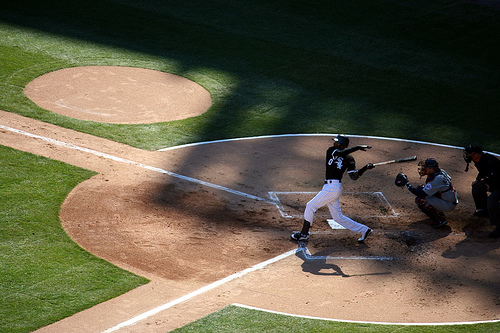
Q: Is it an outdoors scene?
A: Yes, it is outdoors.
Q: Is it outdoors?
A: Yes, it is outdoors.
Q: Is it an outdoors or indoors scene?
A: It is outdoors.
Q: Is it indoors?
A: No, it is outdoors.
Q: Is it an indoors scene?
A: No, it is outdoors.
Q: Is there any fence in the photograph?
A: No, there are no fences.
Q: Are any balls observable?
A: No, there are no balls.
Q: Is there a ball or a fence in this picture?
A: No, there are no balls or fences.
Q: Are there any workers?
A: No, there are no workers.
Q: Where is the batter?
A: The batter is in the field.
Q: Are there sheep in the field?
A: No, there is a batter in the field.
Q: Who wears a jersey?
A: The batter wears a jersey.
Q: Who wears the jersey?
A: The batter wears a jersey.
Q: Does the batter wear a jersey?
A: Yes, the batter wears a jersey.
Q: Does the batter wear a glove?
A: No, the batter wears a jersey.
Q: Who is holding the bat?
A: The batter is holding the bat.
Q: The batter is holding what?
A: The batter is holding the bat.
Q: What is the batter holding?
A: The batter is holding the bat.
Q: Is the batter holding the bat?
A: Yes, the batter is holding the bat.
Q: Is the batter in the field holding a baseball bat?
A: No, the batter is holding the bat.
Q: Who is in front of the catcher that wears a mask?
A: The batter is in front of the catcher.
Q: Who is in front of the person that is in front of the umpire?
A: The batter is in front of the catcher.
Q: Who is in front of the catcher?
A: The batter is in front of the catcher.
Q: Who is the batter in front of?
A: The batter is in front of the catcher.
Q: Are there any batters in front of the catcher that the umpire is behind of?
A: Yes, there is a batter in front of the catcher.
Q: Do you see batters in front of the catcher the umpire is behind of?
A: Yes, there is a batter in front of the catcher.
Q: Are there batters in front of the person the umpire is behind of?
A: Yes, there is a batter in front of the catcher.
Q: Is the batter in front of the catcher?
A: Yes, the batter is in front of the catcher.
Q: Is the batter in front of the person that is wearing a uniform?
A: Yes, the batter is in front of the catcher.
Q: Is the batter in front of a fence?
A: No, the batter is in front of the catcher.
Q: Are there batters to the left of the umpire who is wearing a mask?
A: Yes, there is a batter to the left of the umpire.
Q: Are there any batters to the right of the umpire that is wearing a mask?
A: No, the batter is to the left of the umpire.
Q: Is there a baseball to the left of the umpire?
A: No, there is a batter to the left of the umpire.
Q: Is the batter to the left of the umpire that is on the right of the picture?
A: Yes, the batter is to the left of the umpire.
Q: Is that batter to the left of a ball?
A: No, the batter is to the left of the umpire.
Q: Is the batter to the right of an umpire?
A: No, the batter is to the left of an umpire.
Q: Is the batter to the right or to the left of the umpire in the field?
A: The batter is to the left of the umpire.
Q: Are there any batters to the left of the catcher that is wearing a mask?
A: Yes, there is a batter to the left of the catcher.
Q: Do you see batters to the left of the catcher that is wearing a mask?
A: Yes, there is a batter to the left of the catcher.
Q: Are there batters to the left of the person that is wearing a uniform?
A: Yes, there is a batter to the left of the catcher.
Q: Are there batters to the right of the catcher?
A: No, the batter is to the left of the catcher.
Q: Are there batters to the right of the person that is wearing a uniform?
A: No, the batter is to the left of the catcher.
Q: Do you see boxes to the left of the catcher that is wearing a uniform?
A: No, there is a batter to the left of the catcher.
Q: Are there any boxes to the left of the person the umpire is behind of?
A: No, there is a batter to the left of the catcher.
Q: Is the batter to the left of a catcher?
A: Yes, the batter is to the left of a catcher.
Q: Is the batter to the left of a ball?
A: No, the batter is to the left of a catcher.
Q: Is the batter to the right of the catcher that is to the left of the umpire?
A: No, the batter is to the left of the catcher.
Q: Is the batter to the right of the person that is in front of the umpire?
A: No, the batter is to the left of the catcher.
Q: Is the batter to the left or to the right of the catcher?
A: The batter is to the left of the catcher.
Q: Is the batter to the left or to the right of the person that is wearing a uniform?
A: The batter is to the left of the catcher.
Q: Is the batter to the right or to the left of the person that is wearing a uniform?
A: The batter is to the left of the catcher.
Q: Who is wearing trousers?
A: The batter is wearing trousers.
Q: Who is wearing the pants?
A: The batter is wearing trousers.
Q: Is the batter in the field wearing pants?
A: Yes, the batter is wearing pants.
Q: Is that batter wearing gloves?
A: No, the batter is wearing pants.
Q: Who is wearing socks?
A: The batter is wearing socks.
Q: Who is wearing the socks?
A: The batter is wearing socks.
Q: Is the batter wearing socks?
A: Yes, the batter is wearing socks.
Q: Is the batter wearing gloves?
A: No, the batter is wearing socks.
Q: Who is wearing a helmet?
A: The batter is wearing a helmet.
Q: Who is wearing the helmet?
A: The batter is wearing a helmet.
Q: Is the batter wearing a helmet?
A: Yes, the batter is wearing a helmet.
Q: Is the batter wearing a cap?
A: No, the batter is wearing a helmet.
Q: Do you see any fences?
A: No, there are no fences.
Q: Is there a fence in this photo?
A: No, there are no fences.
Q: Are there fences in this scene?
A: No, there are no fences.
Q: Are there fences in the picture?
A: No, there are no fences.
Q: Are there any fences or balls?
A: No, there are no fences or balls.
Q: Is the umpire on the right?
A: Yes, the umpire is on the right of the image.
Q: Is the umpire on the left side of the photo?
A: No, the umpire is on the right of the image.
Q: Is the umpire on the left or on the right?
A: The umpire is on the right of the image.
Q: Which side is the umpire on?
A: The umpire is on the right of the image.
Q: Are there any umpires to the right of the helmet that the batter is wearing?
A: Yes, there is an umpire to the right of the helmet.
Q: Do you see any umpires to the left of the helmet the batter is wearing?
A: No, the umpire is to the right of the helmet.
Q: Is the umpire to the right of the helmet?
A: Yes, the umpire is to the right of the helmet.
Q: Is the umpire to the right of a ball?
A: No, the umpire is to the right of the helmet.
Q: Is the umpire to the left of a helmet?
A: No, the umpire is to the right of a helmet.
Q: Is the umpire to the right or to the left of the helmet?
A: The umpire is to the right of the helmet.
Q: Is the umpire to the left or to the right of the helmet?
A: The umpire is to the right of the helmet.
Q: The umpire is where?
A: The umpire is in the field.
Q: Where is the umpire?
A: The umpire is in the field.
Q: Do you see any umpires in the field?
A: Yes, there is an umpire in the field.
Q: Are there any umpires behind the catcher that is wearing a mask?
A: Yes, there is an umpire behind the catcher.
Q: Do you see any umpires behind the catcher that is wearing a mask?
A: Yes, there is an umpire behind the catcher.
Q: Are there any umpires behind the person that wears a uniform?
A: Yes, there is an umpire behind the catcher.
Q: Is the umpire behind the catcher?
A: Yes, the umpire is behind the catcher.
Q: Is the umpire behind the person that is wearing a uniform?
A: Yes, the umpire is behind the catcher.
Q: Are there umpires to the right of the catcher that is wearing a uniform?
A: Yes, there is an umpire to the right of the catcher.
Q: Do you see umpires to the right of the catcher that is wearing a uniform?
A: Yes, there is an umpire to the right of the catcher.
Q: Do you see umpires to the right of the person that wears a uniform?
A: Yes, there is an umpire to the right of the catcher.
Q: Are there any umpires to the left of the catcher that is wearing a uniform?
A: No, the umpire is to the right of the catcher.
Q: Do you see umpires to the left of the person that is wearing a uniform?
A: No, the umpire is to the right of the catcher.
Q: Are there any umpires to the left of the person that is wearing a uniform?
A: No, the umpire is to the right of the catcher.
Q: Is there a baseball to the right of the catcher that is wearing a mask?
A: No, there is an umpire to the right of the catcher.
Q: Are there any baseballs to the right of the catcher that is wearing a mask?
A: No, there is an umpire to the right of the catcher.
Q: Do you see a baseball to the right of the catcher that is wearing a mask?
A: No, there is an umpire to the right of the catcher.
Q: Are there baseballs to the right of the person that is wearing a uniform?
A: No, there is an umpire to the right of the catcher.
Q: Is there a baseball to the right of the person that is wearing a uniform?
A: No, there is an umpire to the right of the catcher.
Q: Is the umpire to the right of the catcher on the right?
A: Yes, the umpire is to the right of the catcher.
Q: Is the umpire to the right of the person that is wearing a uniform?
A: Yes, the umpire is to the right of the catcher.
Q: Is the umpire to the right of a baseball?
A: No, the umpire is to the right of the catcher.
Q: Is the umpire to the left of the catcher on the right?
A: No, the umpire is to the right of the catcher.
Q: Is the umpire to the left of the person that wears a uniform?
A: No, the umpire is to the right of the catcher.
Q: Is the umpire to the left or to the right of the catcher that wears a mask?
A: The umpire is to the right of the catcher.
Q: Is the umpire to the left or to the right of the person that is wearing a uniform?
A: The umpire is to the right of the catcher.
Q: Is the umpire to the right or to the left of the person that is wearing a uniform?
A: The umpire is to the right of the catcher.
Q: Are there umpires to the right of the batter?
A: Yes, there is an umpire to the right of the batter.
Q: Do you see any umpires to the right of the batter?
A: Yes, there is an umpire to the right of the batter.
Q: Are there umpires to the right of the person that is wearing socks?
A: Yes, there is an umpire to the right of the batter.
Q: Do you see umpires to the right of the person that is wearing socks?
A: Yes, there is an umpire to the right of the batter.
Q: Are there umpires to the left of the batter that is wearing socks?
A: No, the umpire is to the right of the batter.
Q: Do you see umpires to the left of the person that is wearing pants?
A: No, the umpire is to the right of the batter.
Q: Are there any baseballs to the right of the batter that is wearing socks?
A: No, there is an umpire to the right of the batter.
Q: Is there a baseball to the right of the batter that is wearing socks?
A: No, there is an umpire to the right of the batter.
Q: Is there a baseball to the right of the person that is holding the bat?
A: No, there is an umpire to the right of the batter.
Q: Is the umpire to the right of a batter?
A: Yes, the umpire is to the right of a batter.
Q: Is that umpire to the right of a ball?
A: No, the umpire is to the right of a batter.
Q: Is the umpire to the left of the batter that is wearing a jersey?
A: No, the umpire is to the right of the batter.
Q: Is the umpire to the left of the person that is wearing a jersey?
A: No, the umpire is to the right of the batter.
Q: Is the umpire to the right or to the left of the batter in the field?
A: The umpire is to the right of the batter.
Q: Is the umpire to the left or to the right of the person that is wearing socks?
A: The umpire is to the right of the batter.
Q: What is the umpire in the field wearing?
A: The umpire is wearing a mask.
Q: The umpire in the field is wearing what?
A: The umpire is wearing a mask.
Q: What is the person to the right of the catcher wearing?
A: The umpire is wearing a mask.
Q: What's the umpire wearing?
A: The umpire is wearing a mask.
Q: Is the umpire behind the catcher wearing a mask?
A: Yes, the umpire is wearing a mask.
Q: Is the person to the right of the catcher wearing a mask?
A: Yes, the umpire is wearing a mask.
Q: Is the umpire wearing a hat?
A: No, the umpire is wearing a mask.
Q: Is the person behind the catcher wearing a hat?
A: No, the umpire is wearing a mask.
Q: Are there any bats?
A: Yes, there is a bat.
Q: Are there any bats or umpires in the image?
A: Yes, there is a bat.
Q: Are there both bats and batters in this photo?
A: Yes, there are both a bat and a batter.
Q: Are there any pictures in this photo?
A: No, there are no pictures.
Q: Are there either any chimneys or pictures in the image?
A: No, there are no pictures or chimneys.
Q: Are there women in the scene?
A: No, there are no women.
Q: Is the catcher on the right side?
A: Yes, the catcher is on the right of the image.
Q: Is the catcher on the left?
A: No, the catcher is on the right of the image.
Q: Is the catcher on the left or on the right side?
A: The catcher is on the right of the image.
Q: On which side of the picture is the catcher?
A: The catcher is on the right of the image.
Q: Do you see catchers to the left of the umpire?
A: Yes, there is a catcher to the left of the umpire.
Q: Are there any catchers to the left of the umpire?
A: Yes, there is a catcher to the left of the umpire.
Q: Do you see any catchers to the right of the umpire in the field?
A: No, the catcher is to the left of the umpire.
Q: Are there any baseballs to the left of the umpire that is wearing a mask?
A: No, there is a catcher to the left of the umpire.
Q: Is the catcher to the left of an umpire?
A: Yes, the catcher is to the left of an umpire.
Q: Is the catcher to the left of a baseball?
A: No, the catcher is to the left of an umpire.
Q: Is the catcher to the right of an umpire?
A: No, the catcher is to the left of an umpire.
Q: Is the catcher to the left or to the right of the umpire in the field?
A: The catcher is to the left of the umpire.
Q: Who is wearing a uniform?
A: The catcher is wearing a uniform.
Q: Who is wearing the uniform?
A: The catcher is wearing a uniform.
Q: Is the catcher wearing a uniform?
A: Yes, the catcher is wearing a uniform.